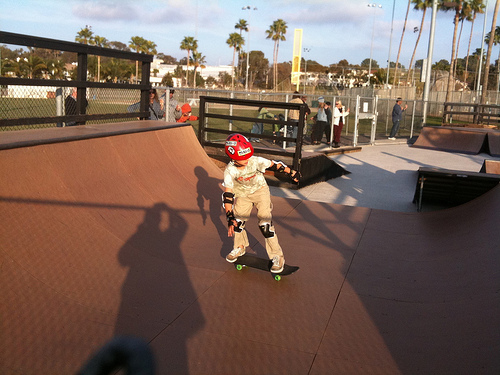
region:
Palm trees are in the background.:
[214, 15, 289, 78]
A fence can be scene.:
[0, 42, 171, 137]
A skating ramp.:
[2, 100, 224, 333]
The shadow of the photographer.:
[74, 182, 212, 362]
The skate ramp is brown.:
[0, 110, 195, 310]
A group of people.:
[266, 81, 418, 162]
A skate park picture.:
[10, 28, 495, 319]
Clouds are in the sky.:
[311, 8, 381, 55]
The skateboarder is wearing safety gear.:
[197, 123, 317, 285]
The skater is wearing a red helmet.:
[201, 125, 315, 289]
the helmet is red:
[211, 114, 321, 199]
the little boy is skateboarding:
[209, 123, 330, 285]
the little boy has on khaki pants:
[223, 181, 325, 288]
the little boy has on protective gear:
[205, 196, 297, 254]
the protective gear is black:
[205, 188, 300, 251]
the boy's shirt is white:
[211, 161, 307, 196]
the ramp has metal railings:
[3, 25, 324, 167]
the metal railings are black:
[0, 22, 321, 181]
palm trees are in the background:
[76, 0, 356, 105]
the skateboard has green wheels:
[226, 244, 302, 304]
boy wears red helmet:
[214, 126, 272, 186]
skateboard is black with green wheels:
[219, 234, 310, 282]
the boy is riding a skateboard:
[213, 126, 307, 298]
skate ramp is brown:
[5, 37, 492, 372]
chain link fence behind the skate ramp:
[5, 78, 495, 170]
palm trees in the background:
[7, 0, 499, 157]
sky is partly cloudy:
[4, 2, 496, 99]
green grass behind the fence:
[3, 87, 498, 145]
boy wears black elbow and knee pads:
[211, 120, 320, 292]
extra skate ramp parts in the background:
[215, 85, 497, 200]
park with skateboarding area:
[1, 0, 499, 372]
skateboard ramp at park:
[1, 115, 499, 372]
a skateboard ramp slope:
[1, 120, 221, 277]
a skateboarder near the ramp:
[217, 130, 304, 283]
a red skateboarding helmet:
[223, 131, 254, 162]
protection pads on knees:
[234, 217, 278, 239]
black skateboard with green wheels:
[236, 252, 302, 284]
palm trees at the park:
[180, 17, 290, 99]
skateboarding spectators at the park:
[286, 89, 350, 149]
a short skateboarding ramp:
[410, 121, 489, 155]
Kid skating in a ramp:
[200, 118, 317, 288]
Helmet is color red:
[218, 124, 259, 172]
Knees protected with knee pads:
[218, 212, 282, 242]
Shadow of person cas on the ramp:
[105, 185, 215, 372]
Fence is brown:
[10, 17, 160, 132]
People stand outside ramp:
[276, 80, 407, 155]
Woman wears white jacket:
[326, 93, 349, 139]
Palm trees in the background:
[172, 5, 293, 90]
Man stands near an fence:
[381, 92, 415, 146]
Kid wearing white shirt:
[212, 124, 314, 285]